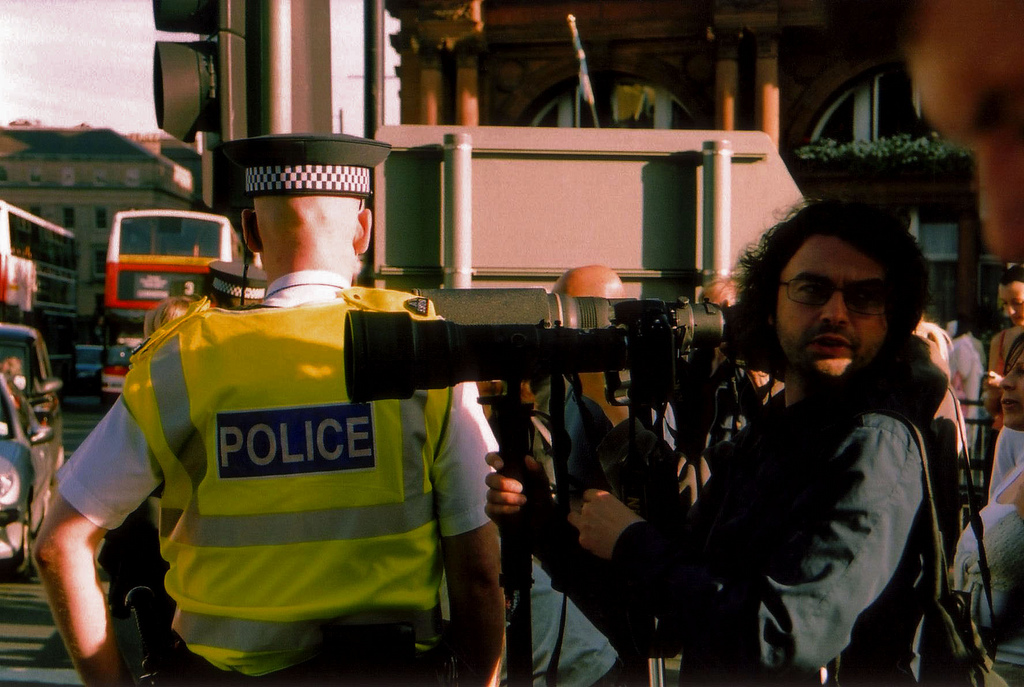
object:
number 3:
[176, 272, 200, 302]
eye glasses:
[770, 270, 894, 319]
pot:
[785, 162, 985, 226]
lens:
[340, 300, 368, 412]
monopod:
[469, 374, 549, 596]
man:
[28, 127, 510, 684]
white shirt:
[54, 265, 506, 547]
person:
[978, 249, 1021, 392]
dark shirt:
[529, 386, 932, 681]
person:
[978, 257, 1021, 410]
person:
[948, 329, 1017, 681]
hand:
[476, 440, 556, 523]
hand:
[566, 475, 649, 562]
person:
[970, 260, 1020, 432]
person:
[944, 329, 1023, 683]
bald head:
[525, 257, 623, 302]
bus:
[99, 205, 239, 398]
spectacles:
[774, 268, 898, 313]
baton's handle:
[124, 581, 179, 684]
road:
[2, 407, 112, 684]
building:
[5, 118, 205, 321]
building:
[378, 3, 1021, 335]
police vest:
[113, 278, 458, 678]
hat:
[189, 120, 452, 193]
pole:
[539, 363, 632, 560]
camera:
[539, 363, 632, 560]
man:
[581, 219, 1010, 682]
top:
[581, 407, 1010, 683]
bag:
[879, 421, 1007, 614]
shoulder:
[879, 421, 1007, 614]